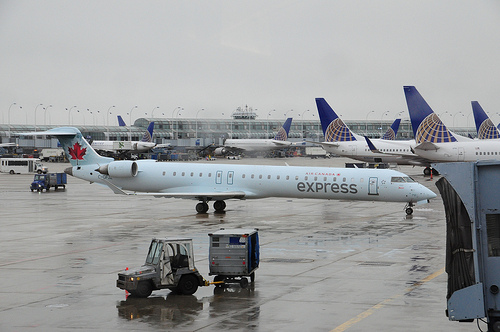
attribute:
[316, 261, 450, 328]
painted — long, yellow, Striped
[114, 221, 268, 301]
truck — luggage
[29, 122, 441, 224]
airplane — white, jet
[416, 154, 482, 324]
jetway — unused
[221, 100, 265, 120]
tower — control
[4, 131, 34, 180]
bus — white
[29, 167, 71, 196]
truck — blue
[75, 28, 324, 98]
skies — grey, gloomy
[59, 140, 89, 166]
leaf — red, oak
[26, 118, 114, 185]
plane — one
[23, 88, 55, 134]
lightpost — one, tall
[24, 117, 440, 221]
plane — one, white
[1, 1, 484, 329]
day — rainy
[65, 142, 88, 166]
emblem — maple leaf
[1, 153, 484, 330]
tarmac — wet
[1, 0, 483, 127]
sky — gray, hazy